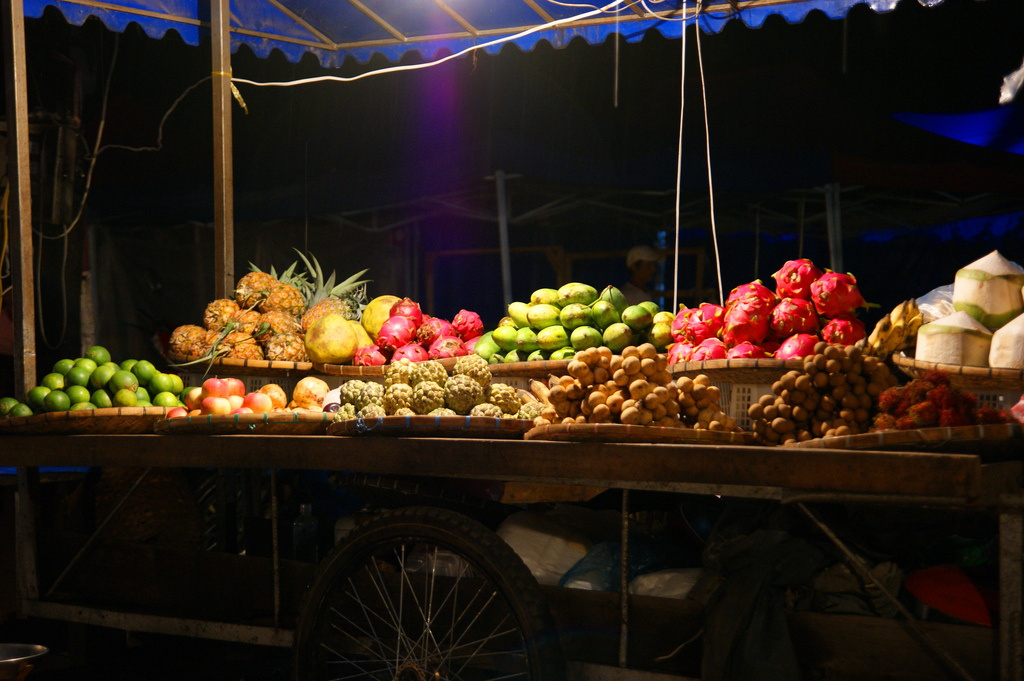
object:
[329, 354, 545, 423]
pineapple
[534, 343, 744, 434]
potato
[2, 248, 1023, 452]
stand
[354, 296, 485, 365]
cabbage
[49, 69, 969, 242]
wall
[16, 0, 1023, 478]
building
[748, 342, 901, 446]
potatoes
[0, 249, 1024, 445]
fruit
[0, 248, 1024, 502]
counter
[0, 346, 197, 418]
pears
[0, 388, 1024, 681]
table